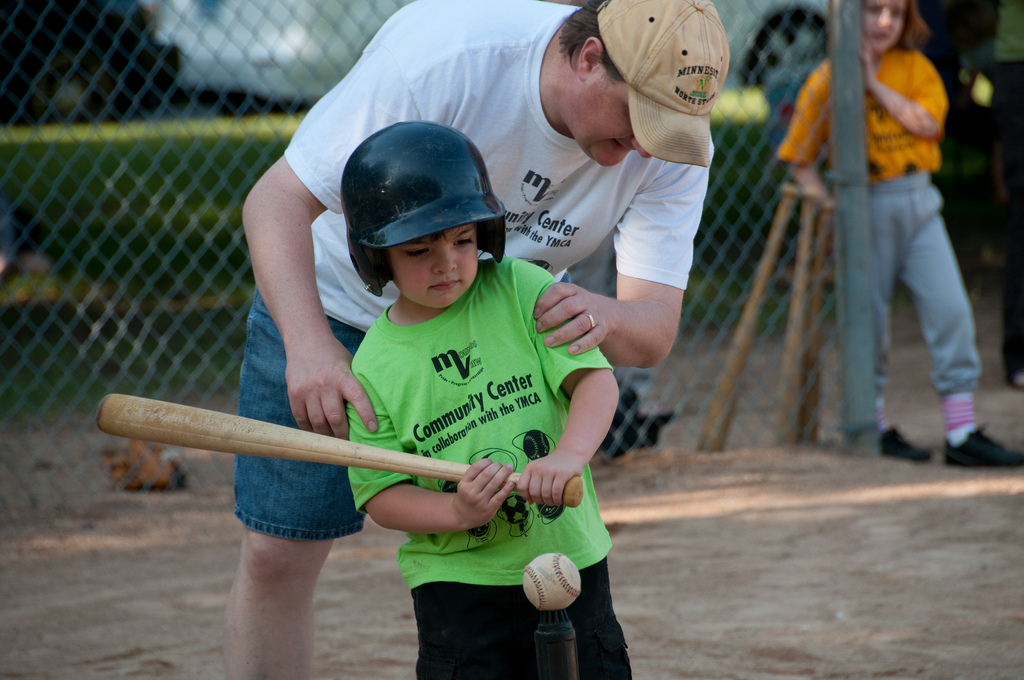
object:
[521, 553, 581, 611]
baseball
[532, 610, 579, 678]
tee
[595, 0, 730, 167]
hat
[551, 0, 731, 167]
head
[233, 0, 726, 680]
man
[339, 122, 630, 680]
boy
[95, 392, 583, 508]
baseball bat